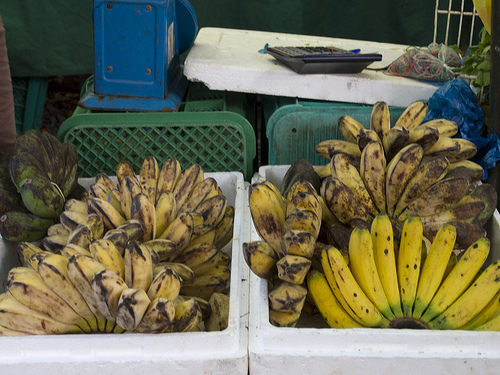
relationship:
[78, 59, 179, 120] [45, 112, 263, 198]
box on crate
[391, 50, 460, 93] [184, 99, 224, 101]
bands on lids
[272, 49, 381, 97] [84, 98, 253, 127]
calculator on table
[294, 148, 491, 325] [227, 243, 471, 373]
bananas in tub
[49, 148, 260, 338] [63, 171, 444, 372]
bananas in tubs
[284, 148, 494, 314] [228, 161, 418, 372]
fruit in box